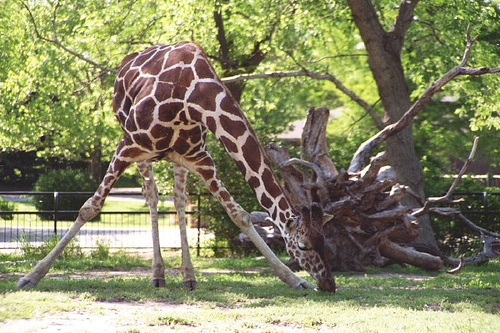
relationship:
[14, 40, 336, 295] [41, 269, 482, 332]
giraffe eating grass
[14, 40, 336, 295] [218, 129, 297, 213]
giraffe has neck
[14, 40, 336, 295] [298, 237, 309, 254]
giraffe has eye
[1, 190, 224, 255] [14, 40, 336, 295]
fence behind giraffe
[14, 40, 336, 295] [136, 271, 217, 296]
giraffe has hooves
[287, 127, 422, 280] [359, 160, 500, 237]
trunk has branches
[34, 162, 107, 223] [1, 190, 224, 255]
shrub near fence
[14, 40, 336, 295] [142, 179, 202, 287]
giraffe has legs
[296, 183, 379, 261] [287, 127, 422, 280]
roots on trunk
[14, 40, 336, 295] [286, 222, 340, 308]
giraffe has head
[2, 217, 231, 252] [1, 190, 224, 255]
road behind fence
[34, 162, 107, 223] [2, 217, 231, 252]
shrub on side of road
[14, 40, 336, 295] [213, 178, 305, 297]
giraffe has leg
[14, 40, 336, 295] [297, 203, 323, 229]
giraffe has horns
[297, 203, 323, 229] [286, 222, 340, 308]
horns on top of head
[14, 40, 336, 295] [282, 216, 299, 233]
giraffe has ear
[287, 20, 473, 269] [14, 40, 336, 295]
tree beside giraffe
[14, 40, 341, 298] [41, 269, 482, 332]
giraffe grazing on grass